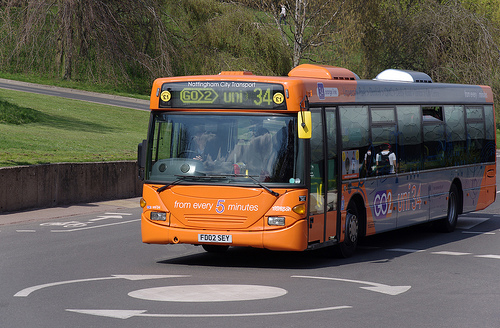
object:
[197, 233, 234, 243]
license plate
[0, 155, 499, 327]
road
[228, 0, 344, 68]
vegetation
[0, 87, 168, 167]
grass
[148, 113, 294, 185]
windscreen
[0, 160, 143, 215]
wall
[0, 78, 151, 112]
street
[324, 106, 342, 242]
door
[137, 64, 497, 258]
bus